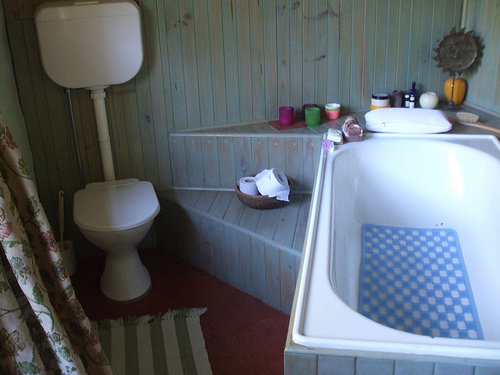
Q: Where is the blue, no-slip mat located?
A: On the bottom of the tub.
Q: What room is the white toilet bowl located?
A: A bathroom.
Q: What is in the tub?
A: Mat.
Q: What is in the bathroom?
A: Curtains.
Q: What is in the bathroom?
A: Basin.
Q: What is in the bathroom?
A: Rug.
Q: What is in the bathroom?
A: Tub.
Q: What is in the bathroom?
A: Toilet.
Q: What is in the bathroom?
A: Rug.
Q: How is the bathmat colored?
A: Blue and white.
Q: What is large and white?
A: Tub.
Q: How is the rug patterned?
A: Stripes.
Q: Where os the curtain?
A: Beside the toilet.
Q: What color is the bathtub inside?
A: White.